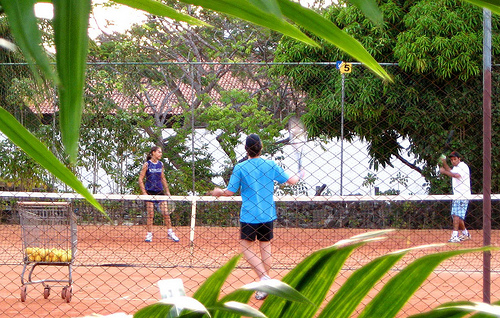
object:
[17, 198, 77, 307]
cart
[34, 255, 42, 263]
balls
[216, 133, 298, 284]
person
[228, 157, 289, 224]
shirt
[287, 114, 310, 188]
racket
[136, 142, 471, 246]
people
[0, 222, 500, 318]
court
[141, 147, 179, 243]
girl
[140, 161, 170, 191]
shirt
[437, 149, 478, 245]
man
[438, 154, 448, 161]
ball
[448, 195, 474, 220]
shorts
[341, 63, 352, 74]
sign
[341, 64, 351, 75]
number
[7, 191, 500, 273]
net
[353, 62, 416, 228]
fence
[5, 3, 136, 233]
plant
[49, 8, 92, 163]
leaves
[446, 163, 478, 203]
shirt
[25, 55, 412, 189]
building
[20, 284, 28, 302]
wheels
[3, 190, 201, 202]
top